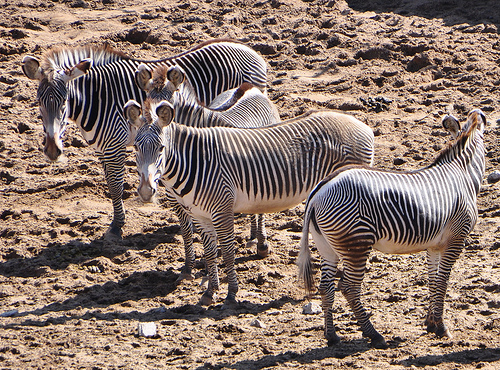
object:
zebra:
[293, 109, 486, 351]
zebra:
[118, 97, 375, 312]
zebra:
[129, 61, 283, 288]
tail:
[293, 200, 321, 301]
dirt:
[0, 0, 498, 369]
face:
[130, 123, 173, 203]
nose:
[131, 183, 159, 199]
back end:
[304, 197, 353, 270]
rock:
[134, 319, 158, 338]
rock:
[301, 300, 324, 315]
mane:
[33, 40, 135, 84]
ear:
[18, 53, 44, 82]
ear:
[63, 56, 94, 83]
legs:
[424, 231, 465, 327]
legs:
[316, 249, 338, 338]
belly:
[371, 236, 434, 254]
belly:
[231, 192, 315, 217]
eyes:
[154, 143, 167, 154]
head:
[121, 98, 176, 204]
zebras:
[16, 40, 273, 242]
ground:
[0, 0, 499, 369]